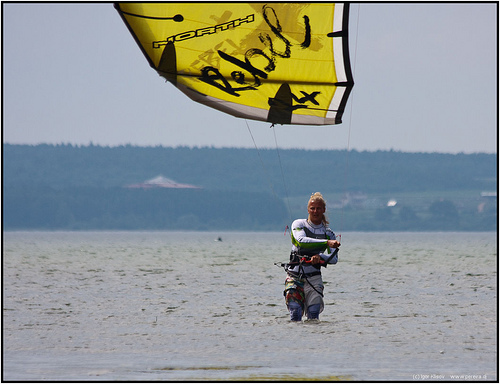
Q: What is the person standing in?
A: Water.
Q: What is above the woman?
A: Sail.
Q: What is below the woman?
A: Water.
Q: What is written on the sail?
A: Rebel.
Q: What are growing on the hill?
A: Trees.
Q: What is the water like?
A: Calm.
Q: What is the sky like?
A: Overcast.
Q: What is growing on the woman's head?
A: Hair.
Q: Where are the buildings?
A: On the hill in the distance.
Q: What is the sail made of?
A: Fabric.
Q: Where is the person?
A: In the water.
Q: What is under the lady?
A: Water.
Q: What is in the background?
A: Trees.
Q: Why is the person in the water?
A: Skiing.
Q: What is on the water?
A: The person.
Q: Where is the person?
A: On the water.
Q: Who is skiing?
A: The person.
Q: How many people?
A: 1.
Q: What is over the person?
A: Glider.